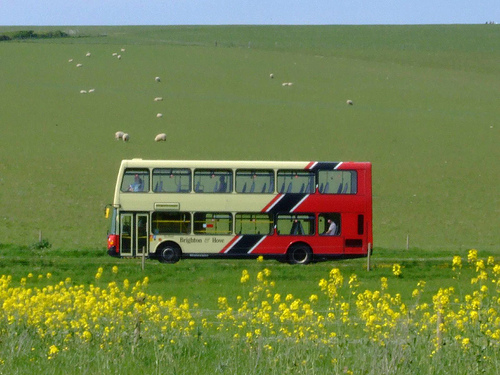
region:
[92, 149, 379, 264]
double decker bus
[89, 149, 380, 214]
second story of the double decker bus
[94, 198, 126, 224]
front side view mirror on the bus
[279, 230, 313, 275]
back black wheel on the us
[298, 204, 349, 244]
man sitting at the back of the bus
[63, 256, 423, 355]
yellow flowers blooming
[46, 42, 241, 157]
herd of sheep grazing in the field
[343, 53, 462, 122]
large grass field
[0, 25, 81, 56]
bushes in the field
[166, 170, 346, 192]
chairs on the bus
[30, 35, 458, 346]
Bus traveling through rural area.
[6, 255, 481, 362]
Tall yellow flowers.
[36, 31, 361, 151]
Sheep grazing in a field.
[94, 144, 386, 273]
A double decker bus.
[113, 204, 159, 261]
Door at front of bus.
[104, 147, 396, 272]
The front of the bus is tan.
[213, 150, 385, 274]
The back of the bus is red.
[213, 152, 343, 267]
Stripe on side of the bus.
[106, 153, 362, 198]
Windows on top of bus.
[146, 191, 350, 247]
Windows on bottom of bus.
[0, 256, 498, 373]
bright yellow flowers in a field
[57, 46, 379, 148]
sheep in a field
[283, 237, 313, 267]
rear tire of a bus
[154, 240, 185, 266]
front tire of a bus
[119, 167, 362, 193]
top windows on a double decker bus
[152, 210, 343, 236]
bottom windows on a double decker bus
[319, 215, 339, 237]
man riding in the rear of a bus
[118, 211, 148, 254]
doors to a bus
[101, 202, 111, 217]
bus mirror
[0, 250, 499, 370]
yellow daisies in the grass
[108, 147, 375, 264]
red, white, and blue bus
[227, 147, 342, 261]
diagonal stripe on side of bus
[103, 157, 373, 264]
double-decker red, white, and blue bus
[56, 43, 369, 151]
white sheep in background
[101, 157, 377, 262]
double-decker bus facing left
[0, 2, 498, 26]
clear blue sky in background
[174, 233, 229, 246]
blue letters on white background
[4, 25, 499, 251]
light green grass in background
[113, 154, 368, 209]
passengers on 2nd floor of bus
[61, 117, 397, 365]
the bus is red and light green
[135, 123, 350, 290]
the bus is red and light green